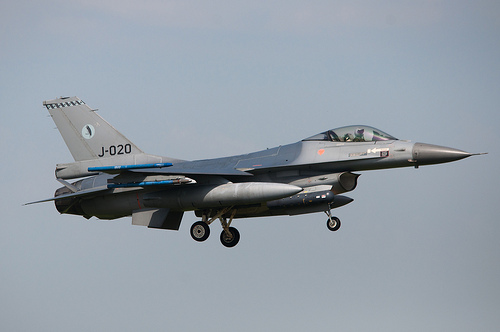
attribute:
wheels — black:
[221, 227, 240, 246]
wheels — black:
[190, 220, 210, 240]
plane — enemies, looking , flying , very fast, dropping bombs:
[48, 87, 476, 248]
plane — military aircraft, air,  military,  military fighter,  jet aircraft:
[13, 87, 496, 244]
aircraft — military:
[65, 84, 392, 304]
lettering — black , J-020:
[96, 138, 138, 160]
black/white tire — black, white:
[323, 213, 342, 230]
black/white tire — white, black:
[186, 220, 211, 242]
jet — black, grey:
[19, 80, 495, 261]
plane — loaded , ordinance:
[66, 80, 417, 267]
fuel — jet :
[137, 182, 347, 220]